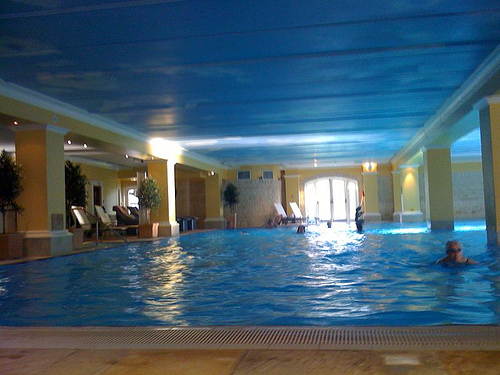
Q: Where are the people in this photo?
A: In the pool.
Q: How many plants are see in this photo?
A: Four.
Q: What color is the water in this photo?
A: Blue.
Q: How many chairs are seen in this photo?
A: Six.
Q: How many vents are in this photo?
A: Two.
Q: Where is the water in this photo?
A: In a pool.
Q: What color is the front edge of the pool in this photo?
A: Brown.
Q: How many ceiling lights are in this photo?
A: Nine.